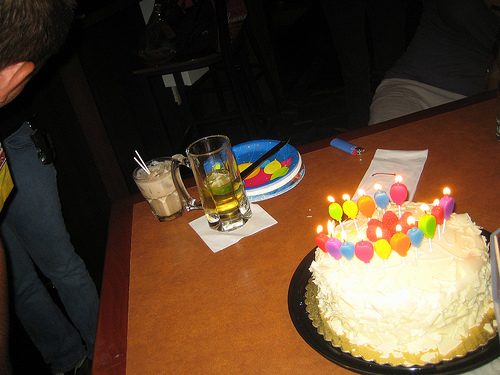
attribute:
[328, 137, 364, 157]
cigarette lighter — blue, red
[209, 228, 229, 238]
paper — thin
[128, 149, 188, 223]
glass — full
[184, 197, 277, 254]
napkin — thin, white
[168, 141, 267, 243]
mug — large, clear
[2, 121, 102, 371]
jeans — blue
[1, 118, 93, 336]
pants — jean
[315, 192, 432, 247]
candles — lighted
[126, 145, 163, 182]
straw — white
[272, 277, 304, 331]
plate — black, round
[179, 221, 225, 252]
napkin — white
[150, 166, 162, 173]
liquid — brown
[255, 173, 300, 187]
plates — blue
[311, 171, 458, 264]
candles — many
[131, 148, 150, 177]
straws — white